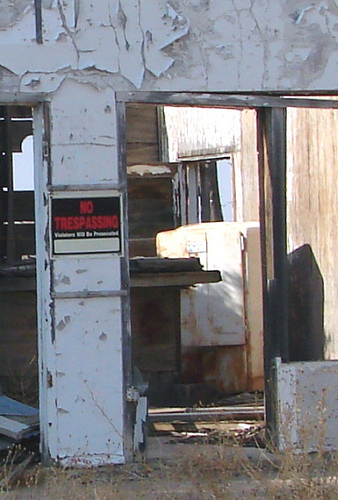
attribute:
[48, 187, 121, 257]
sign — black, white, pictured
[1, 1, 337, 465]
paint — peeling, cracking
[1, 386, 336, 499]
plants — brown, growing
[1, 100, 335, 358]
boards — wooden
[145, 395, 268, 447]
boards — wooden, pictured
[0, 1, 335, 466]
building — dilapidated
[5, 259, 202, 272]
plank — tall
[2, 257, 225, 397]
counter — wooden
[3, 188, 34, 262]
planks — wooden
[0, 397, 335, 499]
ground — pictured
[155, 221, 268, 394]
refrigerator — rusty, old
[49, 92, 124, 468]
wall — broken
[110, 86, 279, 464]
door frame — pictured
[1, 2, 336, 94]
wall — broken